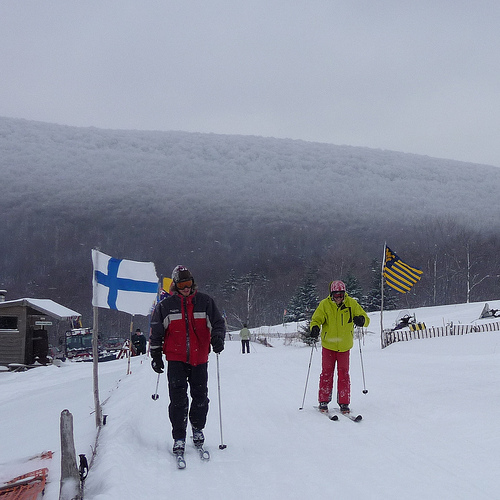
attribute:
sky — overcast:
[2, 4, 494, 179]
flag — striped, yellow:
[381, 245, 423, 294]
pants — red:
[319, 351, 351, 404]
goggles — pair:
[172, 279, 204, 289]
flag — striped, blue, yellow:
[371, 234, 430, 303]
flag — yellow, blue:
[369, 233, 424, 299]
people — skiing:
[148, 263, 226, 453]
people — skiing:
[306, 278, 371, 413]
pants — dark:
[157, 352, 211, 444]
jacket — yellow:
[309, 291, 369, 355]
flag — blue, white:
[89, 248, 158, 315]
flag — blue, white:
[85, 246, 165, 326]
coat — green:
[304, 291, 374, 356]